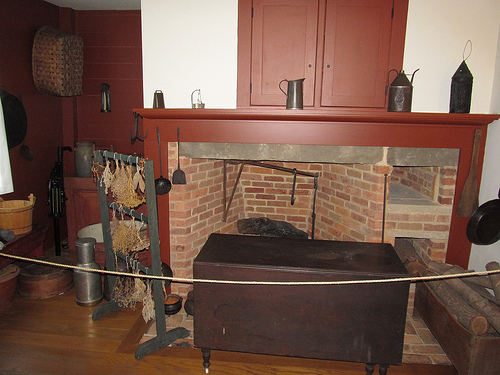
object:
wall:
[0, 1, 500, 372]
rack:
[309, 184, 327, 195]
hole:
[351, 175, 365, 193]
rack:
[192, 127, 320, 182]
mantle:
[127, 101, 498, 301]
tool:
[167, 122, 188, 185]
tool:
[154, 120, 171, 195]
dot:
[309, 64, 312, 67]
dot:
[326, 63, 330, 68]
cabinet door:
[246, 0, 324, 111]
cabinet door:
[317, 2, 395, 108]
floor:
[0, 289, 460, 375]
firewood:
[421, 256, 499, 337]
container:
[387, 234, 500, 375]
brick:
[141, 140, 455, 359]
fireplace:
[157, 138, 456, 321]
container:
[277, 78, 304, 110]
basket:
[34, 31, 86, 99]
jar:
[385, 68, 412, 112]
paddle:
[466, 130, 498, 249]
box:
[189, 229, 406, 375]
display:
[0, 0, 496, 375]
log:
[236, 216, 309, 240]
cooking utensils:
[154, 125, 187, 195]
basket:
[1, 192, 30, 234]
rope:
[1, 250, 498, 286]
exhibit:
[1, 0, 500, 372]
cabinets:
[235, 0, 411, 110]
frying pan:
[464, 200, 500, 245]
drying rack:
[87, 144, 188, 357]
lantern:
[97, 85, 111, 112]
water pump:
[46, 148, 64, 255]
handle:
[53, 145, 72, 167]